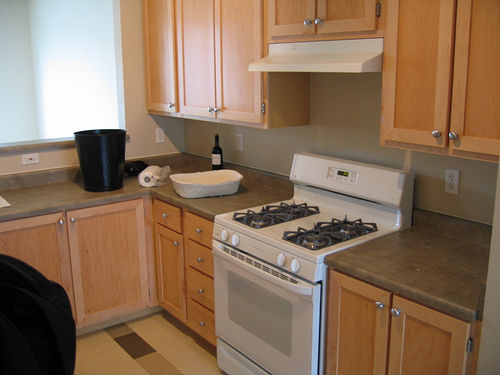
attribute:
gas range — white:
[210, 150, 419, 373]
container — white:
[168, 167, 242, 199]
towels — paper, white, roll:
[131, 158, 181, 194]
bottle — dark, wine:
[206, 127, 226, 173]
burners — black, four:
[229, 186, 383, 264]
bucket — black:
[70, 122, 133, 202]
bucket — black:
[61, 108, 139, 213]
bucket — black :
[67, 121, 137, 195]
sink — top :
[5, 193, 15, 207]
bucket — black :
[74, 123, 137, 194]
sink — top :
[1, 190, 11, 206]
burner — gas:
[210, 186, 351, 256]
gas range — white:
[224, 182, 381, 313]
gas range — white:
[219, 180, 365, 307]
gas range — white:
[197, 191, 355, 372]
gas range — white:
[232, 193, 352, 334]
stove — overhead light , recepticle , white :
[213, 146, 402, 370]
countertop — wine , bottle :
[30, 131, 267, 222]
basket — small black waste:
[69, 122, 135, 190]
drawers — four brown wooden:
[153, 204, 213, 325]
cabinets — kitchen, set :
[140, 0, 270, 115]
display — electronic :
[322, 162, 378, 185]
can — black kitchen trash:
[72, 126, 126, 186]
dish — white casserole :
[160, 161, 249, 196]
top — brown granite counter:
[394, 220, 464, 282]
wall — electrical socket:
[307, 108, 358, 141]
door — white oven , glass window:
[224, 273, 298, 351]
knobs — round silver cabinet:
[269, 253, 325, 270]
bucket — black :
[69, 110, 135, 196]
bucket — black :
[70, 121, 130, 195]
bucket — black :
[70, 124, 140, 202]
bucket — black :
[72, 118, 151, 198]